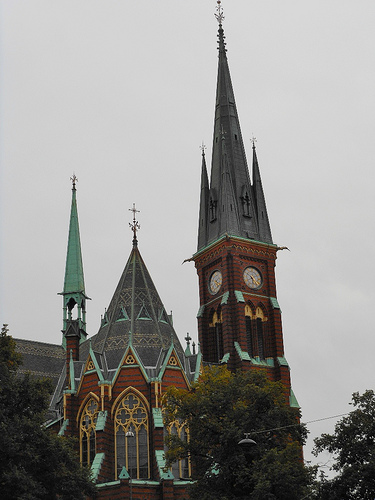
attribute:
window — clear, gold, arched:
[246, 314, 255, 361]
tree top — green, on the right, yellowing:
[159, 365, 311, 499]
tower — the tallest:
[187, 1, 293, 386]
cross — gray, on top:
[129, 203, 143, 222]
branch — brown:
[191, 449, 222, 468]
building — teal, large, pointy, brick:
[3, 2, 312, 499]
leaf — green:
[295, 436, 307, 444]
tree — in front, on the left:
[2, 321, 99, 497]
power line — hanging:
[236, 408, 348, 460]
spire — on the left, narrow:
[62, 172, 91, 339]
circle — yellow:
[131, 407, 146, 426]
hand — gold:
[251, 279, 259, 284]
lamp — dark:
[236, 435, 255, 449]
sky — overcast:
[2, 2, 374, 467]